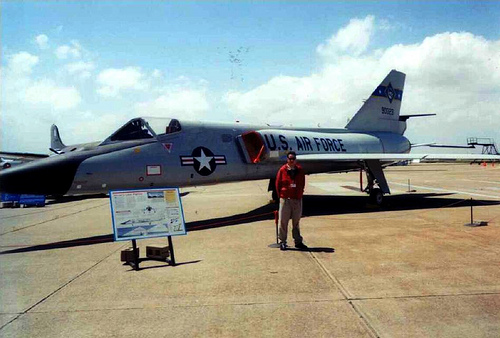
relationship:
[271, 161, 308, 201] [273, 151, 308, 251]
shirt on man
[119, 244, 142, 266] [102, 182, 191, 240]
cinder block holding sign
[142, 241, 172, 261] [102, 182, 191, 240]
cinder block holding sign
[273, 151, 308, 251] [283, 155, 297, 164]
man wearing sunglasses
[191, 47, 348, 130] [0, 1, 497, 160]
clouds in sky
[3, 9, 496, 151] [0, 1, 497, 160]
clouds in sky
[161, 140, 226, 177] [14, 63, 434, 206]
army sign on plane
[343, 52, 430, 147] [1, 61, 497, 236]
tail on plane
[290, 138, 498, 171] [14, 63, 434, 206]
wing on plane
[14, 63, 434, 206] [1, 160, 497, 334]
plane on runway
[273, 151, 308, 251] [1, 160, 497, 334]
man on runway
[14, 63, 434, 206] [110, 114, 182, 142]
plane has windshield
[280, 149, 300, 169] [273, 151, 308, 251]
face of man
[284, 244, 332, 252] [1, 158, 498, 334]
shadow on ground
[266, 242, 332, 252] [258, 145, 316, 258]
shadow of person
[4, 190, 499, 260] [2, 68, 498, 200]
shadow of plane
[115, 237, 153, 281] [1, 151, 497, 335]
stand on floor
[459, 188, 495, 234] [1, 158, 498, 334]
object on ground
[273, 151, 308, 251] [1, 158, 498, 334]
man standing on ground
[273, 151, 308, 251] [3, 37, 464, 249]
man next to plane